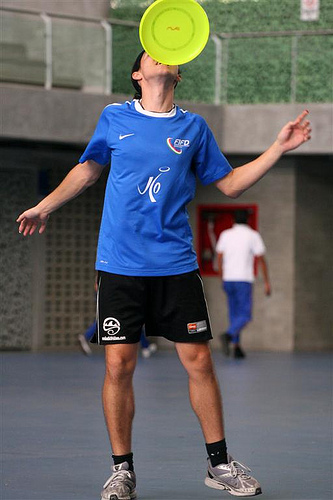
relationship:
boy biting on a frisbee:
[17, 46, 314, 498] [137, 1, 210, 69]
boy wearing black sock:
[17, 46, 314, 498] [206, 439, 228, 464]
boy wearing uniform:
[17, 46, 314, 498] [81, 98, 230, 342]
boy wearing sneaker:
[17, 46, 314, 498] [202, 457, 258, 496]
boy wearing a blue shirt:
[17, 46, 314, 498] [92, 101, 225, 274]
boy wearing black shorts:
[17, 46, 314, 498] [92, 268, 211, 346]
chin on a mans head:
[153, 59, 172, 79] [128, 44, 179, 107]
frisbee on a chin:
[141, 0, 211, 68] [153, 59, 172, 79]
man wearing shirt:
[214, 208, 274, 364] [214, 220, 267, 282]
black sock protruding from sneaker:
[206, 437, 229, 468] [202, 457, 258, 496]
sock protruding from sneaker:
[109, 451, 136, 471] [202, 457, 258, 496]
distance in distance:
[3, 79, 333, 352] [3, 3, 330, 348]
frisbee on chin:
[137, 1, 210, 69] [145, 65, 178, 81]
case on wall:
[196, 203, 261, 281] [1, 134, 331, 353]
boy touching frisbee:
[17, 46, 314, 498] [137, 1, 210, 69]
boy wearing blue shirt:
[17, 46, 314, 498] [92, 101, 225, 274]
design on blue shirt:
[128, 159, 175, 207] [92, 101, 225, 274]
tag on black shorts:
[185, 318, 209, 335] [90, 268, 214, 345]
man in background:
[214, 208, 274, 364] [0, 133, 332, 357]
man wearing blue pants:
[214, 208, 274, 364] [220, 277, 249, 342]